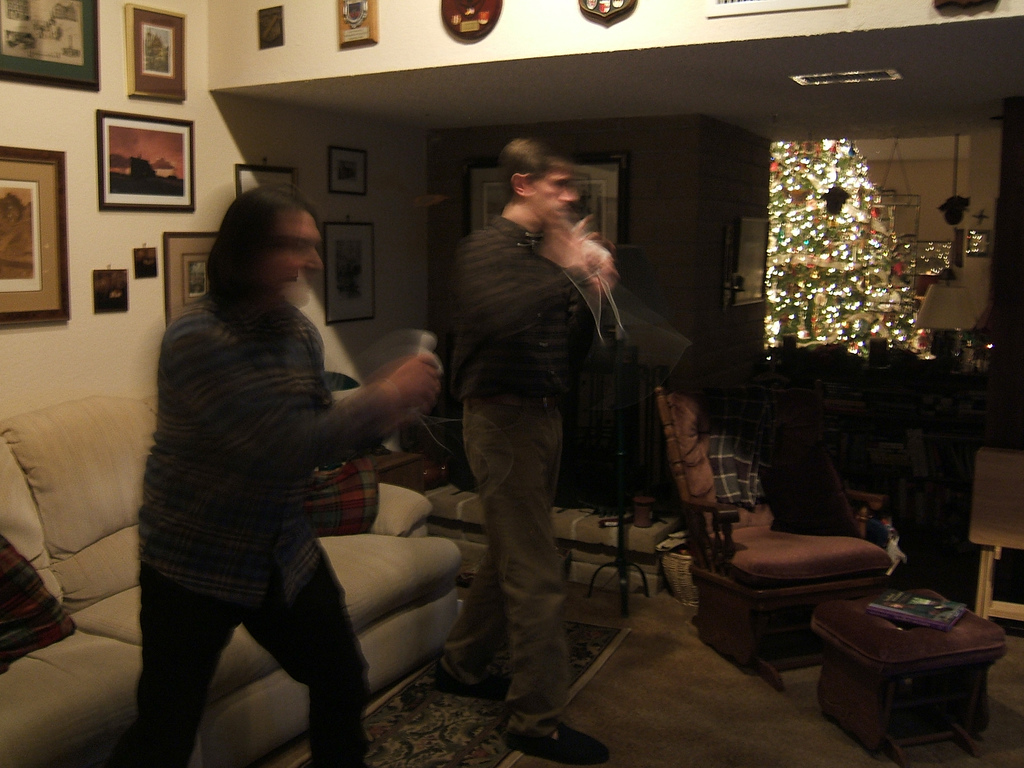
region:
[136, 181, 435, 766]
A man in a plaid shirt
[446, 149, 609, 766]
A man in brown pants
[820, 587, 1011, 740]
A small end table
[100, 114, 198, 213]
A small picture on the wall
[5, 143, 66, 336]
A large picture on the wall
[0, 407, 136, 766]
A tan sofa with pillows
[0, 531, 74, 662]
A red pillow on the sofa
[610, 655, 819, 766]
A brown rug on the floor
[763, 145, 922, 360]
A cluser of lights on the wall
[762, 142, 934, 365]
the christmas tree is large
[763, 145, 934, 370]
the christmas tree is lit up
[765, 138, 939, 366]
the christmas tree is decorated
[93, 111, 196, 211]
the frame is black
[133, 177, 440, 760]
the man is standing up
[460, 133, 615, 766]
the taller man is standing up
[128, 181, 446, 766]
the man is in motion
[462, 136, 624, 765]
the taller man is in motion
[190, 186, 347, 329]
the head of a man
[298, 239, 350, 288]
the nose of a man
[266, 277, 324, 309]
the chin of a man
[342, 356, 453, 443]
the hand of a man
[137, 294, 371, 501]
the arm of a man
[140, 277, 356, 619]
the shirt of a man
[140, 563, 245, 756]
the right leg of a man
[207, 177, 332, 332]
head of a man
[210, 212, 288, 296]
the long hair of a man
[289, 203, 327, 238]
the forehead of a man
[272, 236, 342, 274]
the nose of a man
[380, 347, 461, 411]
the hand of a man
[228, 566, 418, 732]
the left leg of a man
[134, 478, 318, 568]
the belly of a man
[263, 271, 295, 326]
the beard of a man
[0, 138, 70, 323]
picture on the off white wall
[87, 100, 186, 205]
picture on the off white wall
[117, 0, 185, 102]
picture on the off white wall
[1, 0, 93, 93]
picture on the off white wall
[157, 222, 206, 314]
picture on the off white wall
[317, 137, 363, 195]
picture on the off white wall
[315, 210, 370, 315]
picture on the off white wall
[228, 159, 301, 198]
picture on the off white wall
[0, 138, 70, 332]
a picture in a frame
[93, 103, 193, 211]
a picture in a frame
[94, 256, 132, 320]
a picture in a frame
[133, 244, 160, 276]
a picture in a frame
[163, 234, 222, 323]
a picture in a frame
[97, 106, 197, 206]
a picture in a frame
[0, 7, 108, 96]
a picture in a frame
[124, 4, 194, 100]
a picture in a frame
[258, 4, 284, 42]
a picture in a frame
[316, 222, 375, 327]
a picture in a frame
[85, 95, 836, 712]
people standing up in the background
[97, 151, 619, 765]
person holding a white remote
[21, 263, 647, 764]
a couch in the background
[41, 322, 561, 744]
a brown couch in the background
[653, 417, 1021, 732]
chair in the background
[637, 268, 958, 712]
brown chair in the background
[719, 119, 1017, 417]
lights in the background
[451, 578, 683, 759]
black shoes on the ground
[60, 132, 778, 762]
a scene inside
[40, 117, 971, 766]
a scene at a living room